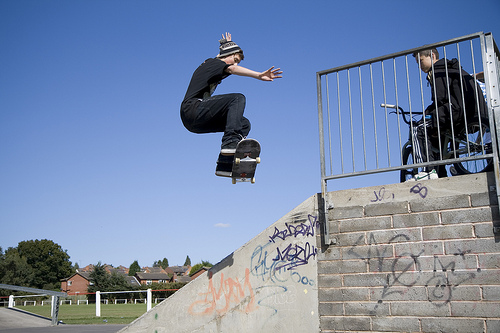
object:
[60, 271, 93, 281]
roof top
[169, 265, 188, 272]
roof top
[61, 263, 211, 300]
house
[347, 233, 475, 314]
writing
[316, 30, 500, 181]
railing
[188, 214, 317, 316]
writing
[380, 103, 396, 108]
handle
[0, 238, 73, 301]
tree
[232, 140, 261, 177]
underside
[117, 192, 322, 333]
ramp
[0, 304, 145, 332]
ground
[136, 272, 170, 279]
roof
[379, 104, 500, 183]
bicycle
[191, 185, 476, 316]
graffiti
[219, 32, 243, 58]
beanie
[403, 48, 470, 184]
boy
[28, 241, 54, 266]
leaves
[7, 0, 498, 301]
air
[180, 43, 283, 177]
boy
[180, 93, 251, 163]
pants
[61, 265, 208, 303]
home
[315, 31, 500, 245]
poles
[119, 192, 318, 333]
cement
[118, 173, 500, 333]
wall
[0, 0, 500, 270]
sky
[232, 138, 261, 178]
skateboard